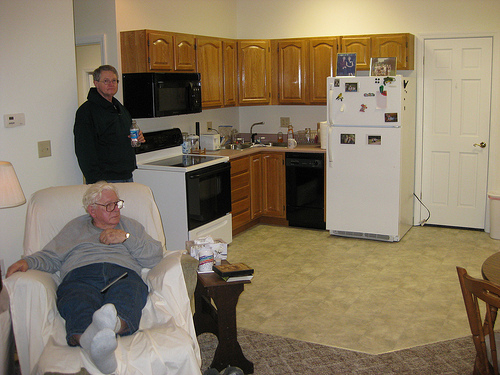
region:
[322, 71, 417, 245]
white refrigerator covered in magnets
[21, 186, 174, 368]
old man sitting on a white recliner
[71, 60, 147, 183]
older man in black jacket drinking a beverage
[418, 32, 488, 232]
white closed door of the room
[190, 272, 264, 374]
small dark brown wooden table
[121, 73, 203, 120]
black microwave attached under the cupboards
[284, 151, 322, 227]
black dishwasher next to the refrigerator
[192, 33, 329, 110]
light brown oak cupboards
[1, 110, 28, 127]
white thermostat on the wall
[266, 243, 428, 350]
cream colored laminate tile floor in the kitchen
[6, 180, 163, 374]
An old man with white hair and glasses.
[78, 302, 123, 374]
White socks on an old man with white hair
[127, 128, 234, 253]
White and black range under the microwave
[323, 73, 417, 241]
A white refridgerator in the kitchen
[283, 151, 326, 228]
A small black dishwasher beside the fridge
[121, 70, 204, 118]
Black microwave above the oven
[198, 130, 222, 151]
A white toaster on the counter by the stove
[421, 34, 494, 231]
A tall white door to the right of a fridge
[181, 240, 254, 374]
A small rectangle top brown side chair table.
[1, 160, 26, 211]
A lampshade to the left of a man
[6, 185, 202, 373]
Old man sitting in a chair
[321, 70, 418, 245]
White fridge with pictures on it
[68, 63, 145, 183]
Man standing carrying water bottle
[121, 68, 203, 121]
A black hanging microwave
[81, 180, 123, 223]
White hair on man's head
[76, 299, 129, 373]
A pair of white socks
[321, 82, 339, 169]
Two handles on a fridge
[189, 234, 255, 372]
Items on a small table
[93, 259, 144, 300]
Remote control on man's lap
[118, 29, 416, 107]
Brown cabinets made of wood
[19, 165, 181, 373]
guy sitting on recliner chair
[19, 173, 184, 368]
white sheet covering recliner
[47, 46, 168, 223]
person standing behind recliner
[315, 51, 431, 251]
white refrigerator with magnets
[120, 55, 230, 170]
black microwave oven over stove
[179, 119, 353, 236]
stuff on kitchen counter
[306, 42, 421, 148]
pictures on top of refrigerator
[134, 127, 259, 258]
black and white stove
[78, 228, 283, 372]
wood end table next to chair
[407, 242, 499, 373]
wood chair and table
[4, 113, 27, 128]
A thermostat on the wall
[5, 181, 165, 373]
A man sitting down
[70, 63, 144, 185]
A man in a black jacket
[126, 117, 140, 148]
A clear drinking bottle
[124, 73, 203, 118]
A black microwave over a stove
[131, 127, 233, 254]
A black and white stove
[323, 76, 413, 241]
A white refrigerator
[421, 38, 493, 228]
A white wooden door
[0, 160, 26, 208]
A white lamp shade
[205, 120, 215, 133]
an electrical outlet